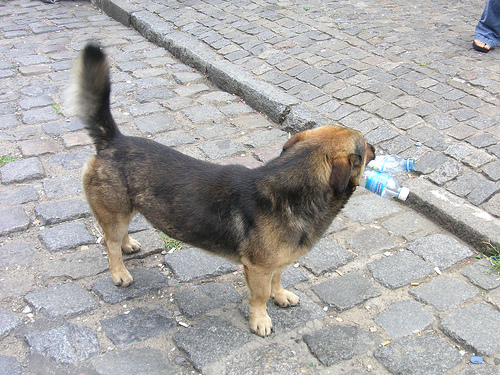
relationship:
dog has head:
[78, 42, 377, 338] [284, 124, 376, 200]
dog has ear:
[78, 42, 377, 338] [334, 151, 362, 195]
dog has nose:
[78, 42, 377, 338] [367, 143, 377, 163]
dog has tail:
[78, 42, 377, 338] [77, 41, 125, 151]